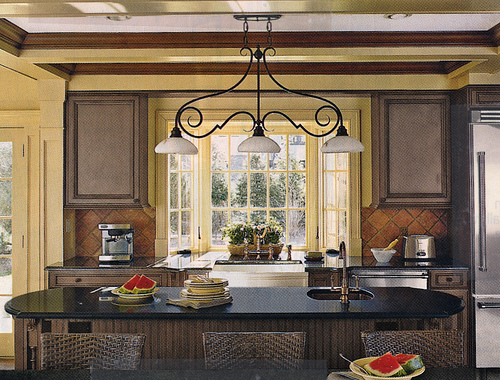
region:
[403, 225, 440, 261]
toaster on the counter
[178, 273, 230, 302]
plates stacked on top of each other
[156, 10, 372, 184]
chandelier hanging from the ceiling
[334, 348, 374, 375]
fork inside the bowl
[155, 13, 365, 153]
an overhead chandelier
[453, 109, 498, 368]
a brushed metal refrigerator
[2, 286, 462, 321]
a black countertop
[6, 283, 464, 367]
a large kitchen island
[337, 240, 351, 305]
a chrome kitchen faucet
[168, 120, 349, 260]
a yellow painted bay window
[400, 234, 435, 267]
a large chrome toaster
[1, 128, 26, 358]
an outside glass paned door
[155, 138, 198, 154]
a white lamp shade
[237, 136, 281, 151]
a white lamp shade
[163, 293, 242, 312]
towels underneath the plate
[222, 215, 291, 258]
Plant in the window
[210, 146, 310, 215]
trees in the backyard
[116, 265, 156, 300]
watermelon on the plate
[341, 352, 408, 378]
bowl on the counter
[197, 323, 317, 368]
chair in front of the table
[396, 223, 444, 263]
toaster on the table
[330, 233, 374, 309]
faucet on the sink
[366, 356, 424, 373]
the watermelon is sliced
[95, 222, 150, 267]
coffee machine on counter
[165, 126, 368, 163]
the light is white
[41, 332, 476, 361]
the chairs are woven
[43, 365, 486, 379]
the table is black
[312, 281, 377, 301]
sink in the island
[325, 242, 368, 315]
faucet above the sink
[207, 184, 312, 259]
plants by the window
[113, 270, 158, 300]
sliced watermelon on a plat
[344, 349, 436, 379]
a bowl of sliced watermelon on a counter top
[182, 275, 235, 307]
a stack of plates on a counter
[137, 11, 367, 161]
a lighting fixture mounted to the cieling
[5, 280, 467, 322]
a black counter top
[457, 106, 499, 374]
a silver refrigerator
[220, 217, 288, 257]
a potted plant sitting near a window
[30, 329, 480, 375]
three wicker chairs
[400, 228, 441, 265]
a silver toaster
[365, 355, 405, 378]
a watermelon slice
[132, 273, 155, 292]
big slice of watermelon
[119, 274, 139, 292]
big slice of watermelon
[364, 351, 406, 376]
big slice of watermelon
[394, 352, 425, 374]
big slice of watermelon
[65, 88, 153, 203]
right brown wooden shelf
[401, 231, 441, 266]
silver toaster in a corner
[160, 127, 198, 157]
White light bulb left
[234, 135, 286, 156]
White light bulb in the middle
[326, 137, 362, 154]
White light bulb right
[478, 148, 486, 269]
fridge gray handle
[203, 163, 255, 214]
wooden window frame in the center